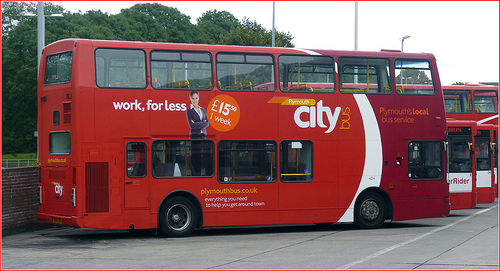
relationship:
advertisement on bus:
[111, 87, 241, 136] [34, 38, 452, 236]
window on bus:
[215, 50, 276, 93] [34, 38, 452, 236]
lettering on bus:
[200, 185, 268, 208] [34, 38, 452, 236]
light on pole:
[47, 9, 66, 21] [36, 1, 49, 74]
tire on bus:
[157, 195, 201, 238] [34, 38, 452, 236]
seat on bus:
[178, 78, 190, 88] [34, 38, 452, 236]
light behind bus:
[47, 9, 66, 21] [34, 38, 452, 236]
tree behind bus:
[0, 14, 91, 157] [34, 38, 452, 236]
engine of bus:
[41, 164, 76, 212] [34, 38, 452, 236]